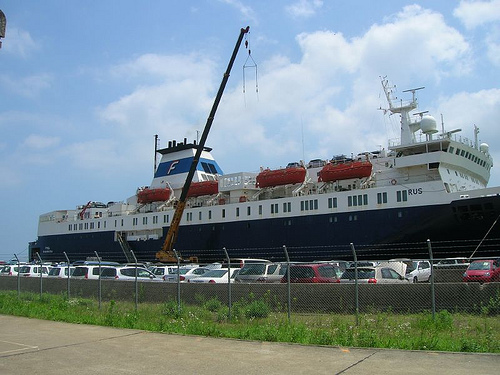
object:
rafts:
[315, 160, 374, 184]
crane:
[156, 17, 262, 263]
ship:
[26, 78, 500, 259]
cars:
[461, 258, 500, 283]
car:
[280, 262, 339, 283]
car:
[235, 262, 287, 283]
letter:
[166, 160, 179, 174]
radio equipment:
[377, 74, 462, 151]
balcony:
[37, 197, 451, 244]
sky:
[11, 0, 150, 184]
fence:
[9, 241, 499, 314]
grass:
[231, 300, 379, 346]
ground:
[0, 313, 496, 375]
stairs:
[127, 258, 137, 262]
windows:
[256, 204, 263, 216]